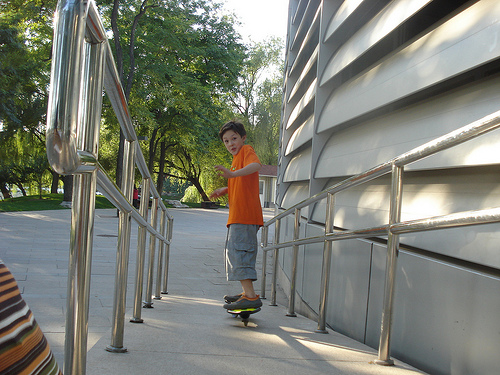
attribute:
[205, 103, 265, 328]
boy — proud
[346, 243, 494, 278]
? — bad sentence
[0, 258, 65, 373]
sleeve — brown, striped, fabric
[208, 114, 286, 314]
boy — young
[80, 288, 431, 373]
sidewalk — paved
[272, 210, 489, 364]
wall — bad sentence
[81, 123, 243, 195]
bad object — bad sentence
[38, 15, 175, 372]
railings — silver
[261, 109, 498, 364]
railings — silver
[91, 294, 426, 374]
ramp — cement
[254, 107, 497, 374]
rail — metal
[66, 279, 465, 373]
patio — gray, cement, tiled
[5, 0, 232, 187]
trees — green